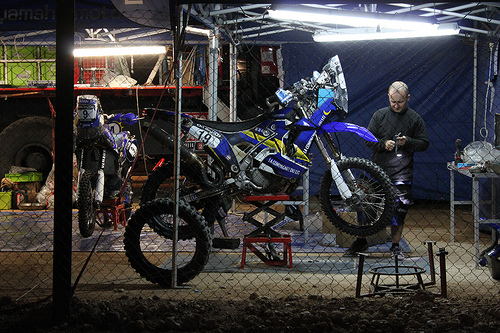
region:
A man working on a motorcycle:
[344, 79, 428, 266]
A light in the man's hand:
[392, 132, 406, 157]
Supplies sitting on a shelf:
[443, 137, 498, 179]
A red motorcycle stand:
[240, 189, 294, 268]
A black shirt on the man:
[366, 104, 431, 184]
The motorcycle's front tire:
[317, 157, 396, 239]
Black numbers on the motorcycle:
[195, 128, 212, 145]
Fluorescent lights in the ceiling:
[267, 4, 459, 45]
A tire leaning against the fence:
[119, 194, 211, 285]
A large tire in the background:
[0, 114, 80, 207]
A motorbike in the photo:
[130, 53, 395, 265]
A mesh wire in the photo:
[251, 179, 371, 316]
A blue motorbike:
[157, 59, 376, 256]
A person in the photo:
[373, 49, 433, 246]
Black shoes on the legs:
[333, 232, 413, 266]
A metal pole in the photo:
[42, 82, 91, 289]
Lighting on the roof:
[347, 17, 445, 44]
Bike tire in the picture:
[320, 151, 404, 243]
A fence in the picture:
[161, 187, 383, 313]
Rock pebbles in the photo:
[225, 302, 305, 330]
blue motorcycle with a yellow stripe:
[140, 53, 397, 235]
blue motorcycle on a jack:
[132, 53, 396, 233]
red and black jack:
[240, 195, 294, 263]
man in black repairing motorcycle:
[345, 80, 428, 256]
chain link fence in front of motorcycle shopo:
[5, 10, 497, 297]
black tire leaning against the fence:
[122, 200, 210, 286]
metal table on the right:
[450, 162, 499, 252]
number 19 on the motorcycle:
[189, 128, 218, 145]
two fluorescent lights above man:
[273, 11, 457, 41]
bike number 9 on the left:
[77, 99, 133, 233]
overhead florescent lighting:
[253, 3, 465, 47]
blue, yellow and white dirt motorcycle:
[128, 51, 398, 243]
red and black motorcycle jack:
[231, 183, 302, 273]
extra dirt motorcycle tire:
[120, 192, 225, 292]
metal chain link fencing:
[2, 0, 498, 330]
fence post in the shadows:
[41, 0, 82, 323]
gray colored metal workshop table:
[441, 156, 498, 274]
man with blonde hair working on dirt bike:
[124, 52, 434, 263]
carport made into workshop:
[1, 3, 498, 313]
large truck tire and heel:
[2, 109, 79, 197]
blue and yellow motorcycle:
[135, 81, 397, 238]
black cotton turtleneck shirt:
[371, 108, 431, 153]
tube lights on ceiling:
[266, 10, 449, 38]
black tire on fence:
[121, 198, 211, 290]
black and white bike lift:
[240, 191, 295, 264]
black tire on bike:
[323, 152, 396, 234]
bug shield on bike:
[321, 53, 351, 115]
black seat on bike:
[188, 111, 272, 131]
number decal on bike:
[192, 127, 217, 149]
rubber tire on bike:
[76, 165, 95, 237]